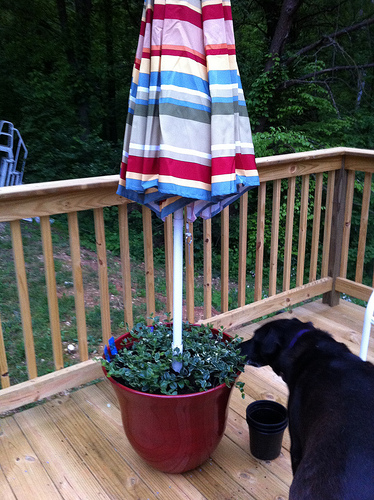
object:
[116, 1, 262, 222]
umbrella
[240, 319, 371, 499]
dog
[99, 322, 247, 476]
flower pot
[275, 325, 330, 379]
dog collar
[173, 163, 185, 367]
pole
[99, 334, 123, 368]
flowers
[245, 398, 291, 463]
container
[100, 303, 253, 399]
plants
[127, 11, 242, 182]
stripes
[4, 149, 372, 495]
deck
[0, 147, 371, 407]
rail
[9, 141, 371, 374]
lawn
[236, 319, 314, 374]
head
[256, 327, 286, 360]
ear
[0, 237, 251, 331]
dirt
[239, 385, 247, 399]
leaf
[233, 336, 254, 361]
nose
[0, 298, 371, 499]
floor